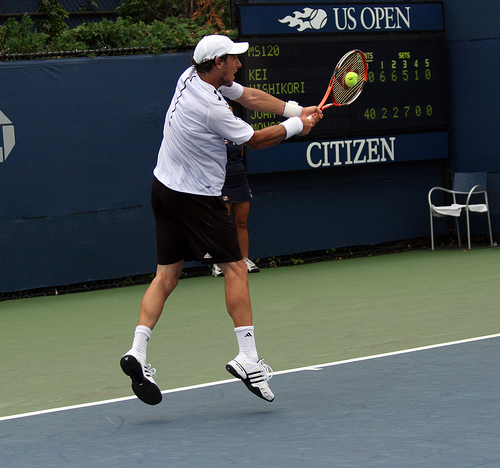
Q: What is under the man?
A: The court.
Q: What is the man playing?
A: Tennis.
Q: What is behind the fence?
A: A bush.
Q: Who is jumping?
A: The man.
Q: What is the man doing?
A: Playing tennis.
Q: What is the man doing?
A: Jumping.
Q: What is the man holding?
A: A racket.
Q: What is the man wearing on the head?
A: Hat.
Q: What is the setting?
A: A tennis court.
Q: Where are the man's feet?
A: Off the ground.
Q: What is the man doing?
A: Jumping and hitting.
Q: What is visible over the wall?
A: Plants.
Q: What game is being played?
A: Tennis.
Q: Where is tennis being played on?
A: A tennis court.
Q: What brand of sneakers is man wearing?
A: Man is wearing adidas sneakers.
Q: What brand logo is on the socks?
A: Adidas logo is on socks.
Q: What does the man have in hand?
A: Man is holding tennis racket.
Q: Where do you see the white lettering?
A: White lettering is on scoreboard.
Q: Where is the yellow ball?
A: The yellow ball is touching the tennis racket.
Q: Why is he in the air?
A: He jumped to hit the ball.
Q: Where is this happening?
A: US Open tournament.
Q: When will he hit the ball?
A: Very soon.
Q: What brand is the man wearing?
A: Adidas.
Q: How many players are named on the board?
A: 2.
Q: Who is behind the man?
A: Tournament official.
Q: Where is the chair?
A: On the right.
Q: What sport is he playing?
A: Tennis.